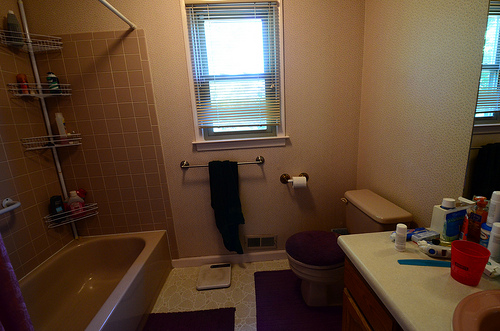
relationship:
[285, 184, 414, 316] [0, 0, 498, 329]
toilet in bathroom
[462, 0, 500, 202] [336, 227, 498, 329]
mirror above vanity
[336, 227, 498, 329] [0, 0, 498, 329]
vanity in bathroom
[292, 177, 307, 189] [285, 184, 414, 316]
napkin by toilet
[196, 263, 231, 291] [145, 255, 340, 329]
scale on floor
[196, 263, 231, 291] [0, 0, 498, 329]
scale in bathroom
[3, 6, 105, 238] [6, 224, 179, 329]
organizer above bathtub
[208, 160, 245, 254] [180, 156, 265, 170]
towel on hanger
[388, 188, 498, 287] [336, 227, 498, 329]
toiletries in vanity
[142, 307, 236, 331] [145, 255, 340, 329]
mat on floor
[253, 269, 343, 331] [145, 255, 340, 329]
rug on floor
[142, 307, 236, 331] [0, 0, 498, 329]
mat in bathroom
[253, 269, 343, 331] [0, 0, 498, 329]
rug in bathroom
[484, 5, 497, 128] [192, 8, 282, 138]
reflection of window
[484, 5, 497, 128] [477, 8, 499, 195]
reflection in mirror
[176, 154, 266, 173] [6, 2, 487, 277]
hanger attached to wall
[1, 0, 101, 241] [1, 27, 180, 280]
rack attached to wall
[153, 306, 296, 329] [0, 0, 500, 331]
mat in bathroom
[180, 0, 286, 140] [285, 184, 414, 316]
blinds next to toilet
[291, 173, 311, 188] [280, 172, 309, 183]
napkin with holder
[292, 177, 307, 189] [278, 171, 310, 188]
napkin on holder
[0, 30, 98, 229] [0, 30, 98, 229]
rack with rack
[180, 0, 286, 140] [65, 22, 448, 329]
blinds in bathroom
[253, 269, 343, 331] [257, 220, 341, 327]
rug for toilet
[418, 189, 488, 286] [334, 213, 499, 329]
items on counter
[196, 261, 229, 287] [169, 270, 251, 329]
scale on floor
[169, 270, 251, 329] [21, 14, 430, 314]
floor of bathroom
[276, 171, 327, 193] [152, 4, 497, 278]
holder attached to wall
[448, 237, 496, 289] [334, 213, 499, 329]
cup on counter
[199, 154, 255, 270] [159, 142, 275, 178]
towel on bar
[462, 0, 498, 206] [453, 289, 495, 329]
mirror above sink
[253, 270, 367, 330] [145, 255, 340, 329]
rug on floor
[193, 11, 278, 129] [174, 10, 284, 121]
blinds on windows